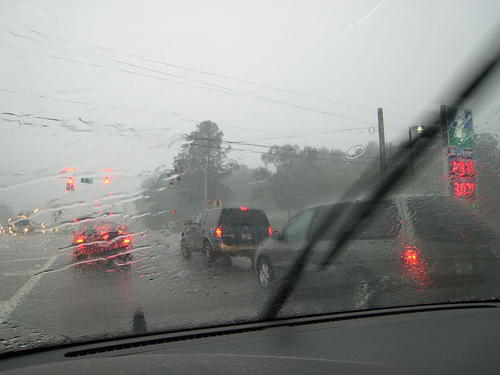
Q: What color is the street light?
A: Red.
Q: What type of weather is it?
A: Rainy.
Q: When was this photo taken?
A: At a stop light.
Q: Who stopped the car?
A: The driver.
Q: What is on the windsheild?
A: Windsheild whippers.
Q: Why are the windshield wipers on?
A: Because it's raining.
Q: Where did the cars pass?
A: A gas station.